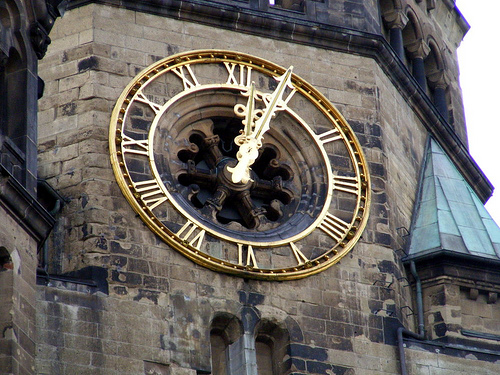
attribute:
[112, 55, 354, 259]
clock — here, goldy, gold, cut, black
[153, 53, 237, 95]
numeral — gold, roman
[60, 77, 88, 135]
building — brick, roof, fancy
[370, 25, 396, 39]
bricks — blue, black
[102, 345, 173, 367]
frisbee — green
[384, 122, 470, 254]
roof — green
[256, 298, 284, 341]
window — curved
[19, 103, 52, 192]
pipes — grey, green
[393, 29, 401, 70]
pillar — dark